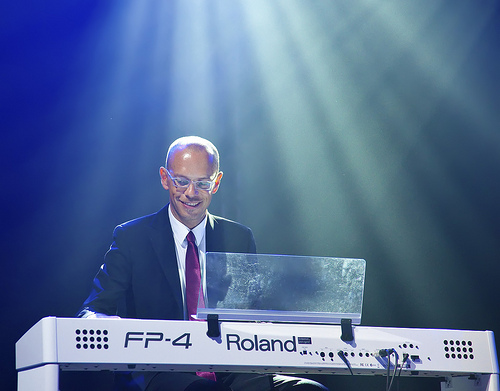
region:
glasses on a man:
[160, 153, 219, 198]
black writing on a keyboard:
[117, 325, 207, 359]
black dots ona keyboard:
[440, 339, 478, 361]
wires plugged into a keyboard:
[301, 342, 424, 367]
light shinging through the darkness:
[365, 190, 435, 257]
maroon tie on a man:
[172, 227, 214, 329]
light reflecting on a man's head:
[165, 131, 218, 168]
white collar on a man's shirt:
[157, 202, 229, 259]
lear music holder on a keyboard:
[187, 248, 371, 328]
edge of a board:
[266, 333, 269, 337]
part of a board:
[310, 251, 319, 277]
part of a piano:
[396, 342, 403, 350]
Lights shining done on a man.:
[64, 0, 494, 323]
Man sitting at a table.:
[78, 133, 260, 317]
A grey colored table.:
[10, 315, 495, 386]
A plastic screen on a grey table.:
[195, 250, 365, 326]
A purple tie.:
[181, 230, 208, 320]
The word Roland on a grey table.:
[224, 330, 299, 355]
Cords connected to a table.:
[334, 345, 414, 384]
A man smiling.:
[81, 130, 266, 314]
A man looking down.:
[77, 133, 287, 317]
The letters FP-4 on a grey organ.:
[116, 328, 192, 349]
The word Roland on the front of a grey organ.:
[220, 330, 295, 355]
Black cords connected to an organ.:
[335, 345, 415, 385]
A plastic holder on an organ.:
[195, 247, 361, 324]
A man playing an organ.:
[5, 134, 495, 384]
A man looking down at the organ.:
[86, 132, 286, 319]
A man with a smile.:
[84, 135, 262, 315]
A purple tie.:
[178, 227, 214, 319]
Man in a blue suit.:
[84, 133, 276, 315]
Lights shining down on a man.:
[5, 3, 494, 317]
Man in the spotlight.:
[15, 132, 497, 386]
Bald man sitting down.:
[77, 133, 266, 315]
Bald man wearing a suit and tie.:
[90, 134, 262, 318]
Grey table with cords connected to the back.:
[10, 314, 499, 379]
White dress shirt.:
[166, 205, 211, 322]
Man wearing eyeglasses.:
[160, 133, 226, 220]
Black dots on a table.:
[73, 323, 110, 353]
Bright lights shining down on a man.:
[6, 3, 488, 316]